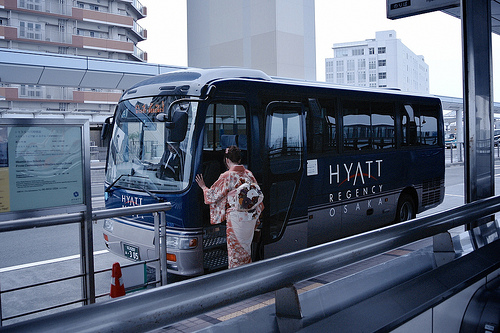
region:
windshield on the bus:
[117, 95, 179, 187]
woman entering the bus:
[201, 155, 262, 262]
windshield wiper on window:
[98, 171, 123, 198]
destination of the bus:
[120, 98, 178, 119]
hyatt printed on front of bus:
[114, 192, 149, 211]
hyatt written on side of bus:
[325, 157, 392, 187]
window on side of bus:
[339, 112, 400, 147]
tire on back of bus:
[397, 195, 416, 223]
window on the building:
[14, 12, 44, 38]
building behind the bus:
[188, 2, 327, 73]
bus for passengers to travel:
[77, 63, 462, 254]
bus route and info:
[113, 98, 171, 123]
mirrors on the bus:
[93, 103, 223, 151]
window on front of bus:
[106, 111, 181, 193]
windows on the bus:
[317, 106, 401, 152]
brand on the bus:
[321, 153, 391, 218]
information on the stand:
[0, 138, 84, 203]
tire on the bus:
[390, 178, 419, 218]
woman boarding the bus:
[193, 141, 274, 261]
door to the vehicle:
[256, 105, 307, 227]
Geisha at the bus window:
[193, 151, 272, 271]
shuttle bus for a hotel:
[91, 73, 452, 273]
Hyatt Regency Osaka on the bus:
[319, 148, 386, 225]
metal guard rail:
[3, 179, 498, 331]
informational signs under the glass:
[1, 112, 88, 230]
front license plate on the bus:
[118, 240, 143, 264]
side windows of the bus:
[266, 95, 444, 168]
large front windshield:
[96, 90, 196, 195]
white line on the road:
[0, 248, 110, 283]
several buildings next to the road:
[1, 3, 446, 146]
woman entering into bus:
[197, 143, 264, 265]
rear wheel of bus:
[395, 197, 412, 221]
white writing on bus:
[323, 157, 390, 214]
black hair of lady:
[222, 145, 244, 167]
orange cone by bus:
[105, 265, 127, 295]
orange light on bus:
[166, 253, 175, 261]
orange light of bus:
[100, 232, 110, 239]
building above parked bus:
[318, 30, 433, 90]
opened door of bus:
[215, 101, 302, 253]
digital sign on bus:
[135, 99, 169, 115]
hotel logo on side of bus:
[326, 158, 385, 217]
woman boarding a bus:
[192, 145, 264, 272]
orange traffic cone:
[107, 263, 125, 300]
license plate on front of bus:
[121, 245, 140, 261]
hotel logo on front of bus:
[118, 193, 145, 218]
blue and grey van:
[100, 67, 445, 279]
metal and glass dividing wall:
[0, 116, 170, 323]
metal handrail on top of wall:
[0, 196, 498, 331]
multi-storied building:
[185, 0, 314, 82]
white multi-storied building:
[324, 29, 431, 91]